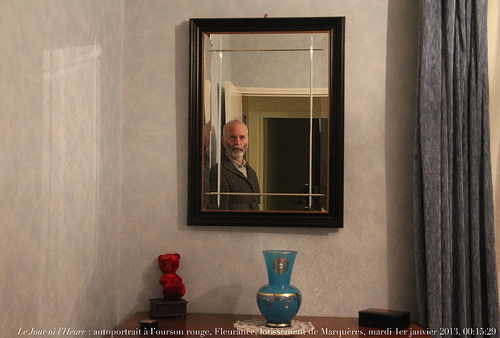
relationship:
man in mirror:
[210, 119, 262, 212] [185, 11, 346, 231]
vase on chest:
[256, 245, 301, 323] [106, 310, 434, 337]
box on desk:
[354, 305, 413, 330] [109, 308, 424, 335]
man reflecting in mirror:
[210, 116, 264, 205] [185, 11, 346, 231]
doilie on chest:
[232, 317, 317, 335] [106, 310, 434, 337]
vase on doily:
[256, 249, 303, 329] [232, 312, 319, 331]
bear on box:
[155, 248, 187, 298] [143, 295, 189, 320]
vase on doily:
[256, 249, 303, 329] [228, 312, 319, 335]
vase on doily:
[256, 249, 303, 329] [233, 314, 315, 332]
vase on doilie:
[256, 249, 303, 329] [232, 317, 317, 335]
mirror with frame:
[200, 30, 328, 210] [185, 14, 346, 230]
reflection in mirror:
[211, 116, 262, 208] [200, 30, 328, 210]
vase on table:
[256, 249, 303, 329] [119, 316, 420, 336]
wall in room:
[6, 41, 136, 322] [1, 0, 473, 330]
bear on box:
[158, 251, 188, 298] [147, 296, 189, 319]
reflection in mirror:
[204, 31, 332, 211] [200, 30, 328, 210]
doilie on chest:
[229, 317, 317, 336] [107, 310, 424, 334]